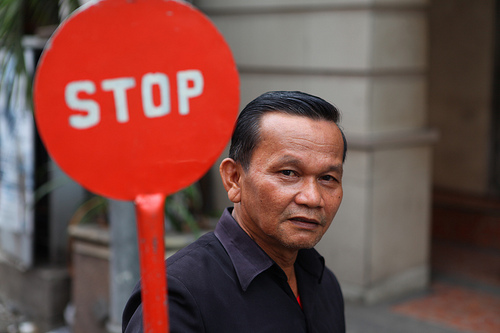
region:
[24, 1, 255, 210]
round stop sign on metal pole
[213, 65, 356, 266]
asian mans face smirking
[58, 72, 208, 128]
the word stop on the sign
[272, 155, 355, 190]
Asian mans eyes staring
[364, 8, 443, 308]
white and gray brick wall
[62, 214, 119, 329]
trash can in the distance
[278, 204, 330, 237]
lips on the mans face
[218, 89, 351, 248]
The man is looking at the camera.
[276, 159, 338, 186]
The man has brown eyes.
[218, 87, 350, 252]
The man has black hair.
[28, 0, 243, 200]
The sign is red and white.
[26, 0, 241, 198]
The sign is round.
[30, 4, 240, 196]
The sign is in English.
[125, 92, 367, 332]
The man is wearing a black shirt.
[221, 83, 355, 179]
Man has black hair combed back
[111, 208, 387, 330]
Man wearing black collared shirt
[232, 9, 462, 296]
Concrete partition behind the man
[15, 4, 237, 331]
Man holding Red stop sign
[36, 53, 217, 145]
Letters written in white on the sign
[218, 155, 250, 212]
Man has crease in earlobe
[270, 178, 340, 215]
Man has a broad nose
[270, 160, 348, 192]
Man has brown eyes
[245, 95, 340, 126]
the hair is neat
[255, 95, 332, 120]
the hair is black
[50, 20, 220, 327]
the sign is red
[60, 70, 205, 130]
the letters are white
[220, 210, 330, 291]
the collar is black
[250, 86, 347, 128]
the hair is cut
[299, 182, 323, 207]
nose on the face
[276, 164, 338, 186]
the eyes on face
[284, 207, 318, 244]
mouth on the face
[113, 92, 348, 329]
this is a person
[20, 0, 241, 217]
this is a sign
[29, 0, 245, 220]
this is a stop sign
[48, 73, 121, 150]
a letter on the sign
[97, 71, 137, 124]
a letter on the sign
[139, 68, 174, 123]
a letter on the sign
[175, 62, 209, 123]
a letter on the sign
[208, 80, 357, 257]
a head of a person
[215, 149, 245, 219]
this is an ear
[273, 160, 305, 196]
this is an eye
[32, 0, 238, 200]
the sign that say's STOP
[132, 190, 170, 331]
the pole attached to the sign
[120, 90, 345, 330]
the man holding the sign